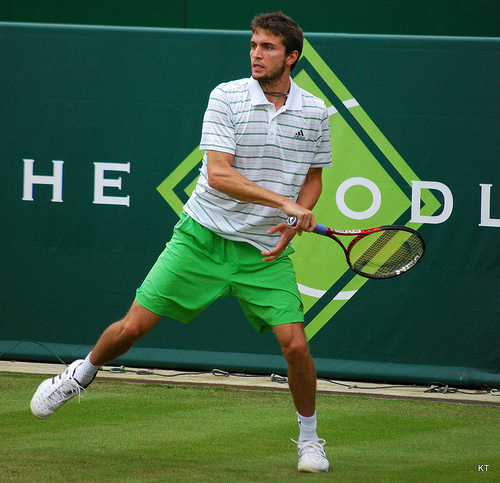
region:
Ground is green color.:
[90, 401, 280, 481]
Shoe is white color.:
[30, 365, 391, 476]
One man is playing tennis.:
[70, 27, 372, 378]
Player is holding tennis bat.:
[280, 205, 426, 290]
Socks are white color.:
[57, 350, 330, 440]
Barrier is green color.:
[15, 75, 458, 336]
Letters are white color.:
[11, 148, 497, 254]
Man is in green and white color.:
[163, 98, 308, 455]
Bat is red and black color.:
[295, 202, 426, 273]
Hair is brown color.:
[262, 10, 302, 37]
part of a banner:
[389, 96, 439, 151]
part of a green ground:
[201, 430, 246, 473]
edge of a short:
[247, 315, 284, 344]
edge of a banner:
[392, 360, 443, 389]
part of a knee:
[115, 313, 136, 339]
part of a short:
[216, 268, 260, 340]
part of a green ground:
[203, 412, 262, 471]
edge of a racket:
[350, 236, 396, 296]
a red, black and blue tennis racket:
[281, 205, 426, 290]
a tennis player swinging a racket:
[25, 9, 431, 471]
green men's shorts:
[128, 206, 308, 335]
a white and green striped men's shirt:
[186, 66, 332, 253]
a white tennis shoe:
[291, 437, 333, 475]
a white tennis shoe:
[21, 352, 98, 422]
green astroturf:
[0, 375, 497, 480]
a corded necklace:
[260, 85, 290, 101]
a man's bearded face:
[241, 9, 305, 93]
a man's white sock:
[290, 404, 320, 445]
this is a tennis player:
[26, 23, 392, 443]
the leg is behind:
[33, 295, 178, 433]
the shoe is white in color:
[34, 377, 69, 412]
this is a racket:
[286, 225, 432, 270]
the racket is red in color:
[348, 222, 379, 258]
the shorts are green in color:
[172, 265, 282, 299]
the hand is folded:
[210, 170, 232, 186]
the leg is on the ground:
[291, 378, 346, 475]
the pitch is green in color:
[403, 431, 464, 480]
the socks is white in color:
[299, 420, 315, 435]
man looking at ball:
[222, 8, 337, 103]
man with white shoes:
[280, 405, 339, 475]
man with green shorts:
[129, 235, 311, 351]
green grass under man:
[116, 388, 228, 473]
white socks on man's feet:
[288, 398, 330, 441]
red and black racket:
[317, 208, 422, 288]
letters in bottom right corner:
[478, 449, 492, 481]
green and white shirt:
[218, 93, 330, 195]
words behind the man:
[29, 121, 153, 227]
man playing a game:
[40, 10, 485, 405]